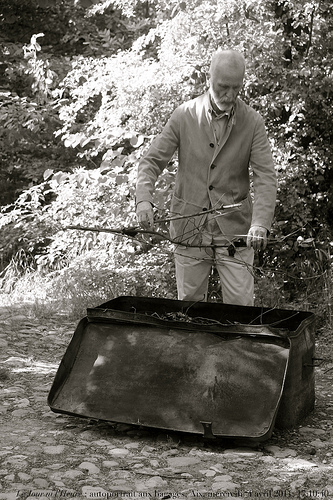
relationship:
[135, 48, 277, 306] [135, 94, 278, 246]
man wearing blazer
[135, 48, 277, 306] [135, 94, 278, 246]
man wearing long sleeve blazer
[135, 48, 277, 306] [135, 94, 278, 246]
man wearing a casual blazer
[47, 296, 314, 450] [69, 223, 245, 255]
box holds branches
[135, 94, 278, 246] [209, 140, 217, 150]
jacket has buttons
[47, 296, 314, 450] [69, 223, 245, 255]
open box with twigs in it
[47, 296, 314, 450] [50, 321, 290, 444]
box has an open lid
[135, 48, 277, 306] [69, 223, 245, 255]
man holds sticks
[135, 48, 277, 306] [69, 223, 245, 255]
man has a branch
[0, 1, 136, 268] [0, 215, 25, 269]
ground has stones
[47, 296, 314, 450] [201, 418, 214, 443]
suitcase has a lock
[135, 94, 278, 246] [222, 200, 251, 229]
jacket has a pocket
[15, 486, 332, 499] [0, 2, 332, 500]
copyright on photo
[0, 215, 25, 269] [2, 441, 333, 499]
stones on ground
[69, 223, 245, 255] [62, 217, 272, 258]
sticks are being held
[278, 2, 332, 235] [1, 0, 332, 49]
bushes in background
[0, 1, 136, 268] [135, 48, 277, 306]
trees behind man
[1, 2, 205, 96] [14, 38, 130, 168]
sunlight hitting leaves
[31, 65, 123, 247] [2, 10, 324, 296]
beams on fauna